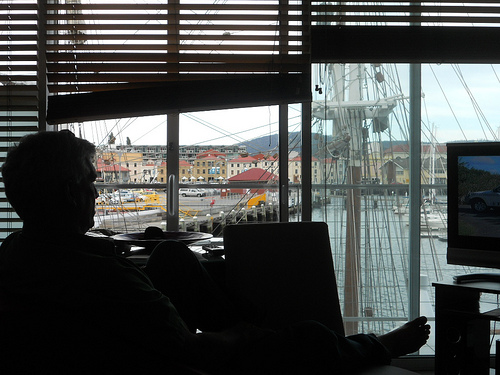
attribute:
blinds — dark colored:
[315, 2, 499, 57]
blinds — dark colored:
[38, 2, 313, 104]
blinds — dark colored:
[0, 1, 35, 223]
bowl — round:
[111, 225, 216, 247]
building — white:
[228, 151, 256, 178]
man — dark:
[0, 127, 194, 369]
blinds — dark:
[48, 23, 499, 125]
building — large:
[116, 153, 143, 184]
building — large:
[194, 152, 226, 182]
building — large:
[229, 151, 257, 180]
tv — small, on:
[445, 139, 499, 269]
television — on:
[444, 140, 498, 273]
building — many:
[96, 140, 338, 203]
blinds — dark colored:
[0, 3, 498, 243]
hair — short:
[2, 128, 97, 222]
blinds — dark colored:
[48, 0, 305, 126]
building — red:
[223, 164, 284, 198]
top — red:
[229, 166, 280, 182]